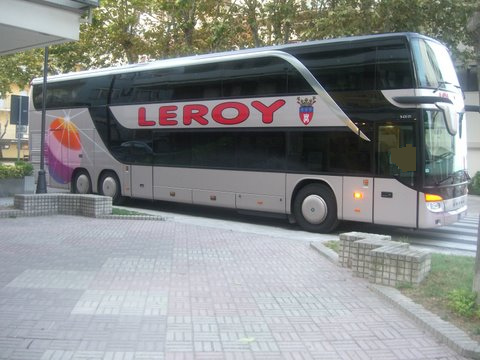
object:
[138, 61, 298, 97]
tinted windows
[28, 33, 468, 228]
bus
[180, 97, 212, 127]
letter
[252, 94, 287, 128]
letter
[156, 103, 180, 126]
letter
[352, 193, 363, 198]
yellow signal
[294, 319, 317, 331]
bricks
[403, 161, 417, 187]
grounds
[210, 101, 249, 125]
letter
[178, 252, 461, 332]
walk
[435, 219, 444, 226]
headlight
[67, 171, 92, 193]
wheels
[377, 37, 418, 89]
window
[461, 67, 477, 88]
window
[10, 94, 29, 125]
window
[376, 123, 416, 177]
window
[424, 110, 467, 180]
window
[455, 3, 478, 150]
building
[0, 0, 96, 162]
building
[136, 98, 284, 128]
leroy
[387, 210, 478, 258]
crosswalk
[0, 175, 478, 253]
street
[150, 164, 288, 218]
luggage compartment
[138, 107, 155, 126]
letter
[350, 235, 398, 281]
bricks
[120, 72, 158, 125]
wall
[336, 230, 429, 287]
block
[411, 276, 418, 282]
brick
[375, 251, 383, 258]
brick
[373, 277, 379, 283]
brick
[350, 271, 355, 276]
brick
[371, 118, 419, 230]
front door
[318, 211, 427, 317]
concrete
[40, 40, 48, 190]
lamppost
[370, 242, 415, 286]
block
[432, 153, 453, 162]
steering wheel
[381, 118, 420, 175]
cockpit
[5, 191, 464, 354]
sidewalk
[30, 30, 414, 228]
side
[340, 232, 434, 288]
seating area